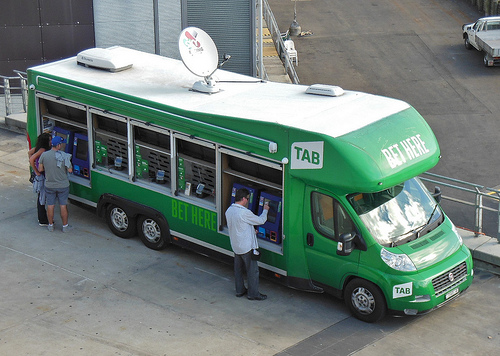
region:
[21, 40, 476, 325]
A big green truck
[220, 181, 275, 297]
A person standing near the truck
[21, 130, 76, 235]
Two people standing together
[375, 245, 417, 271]
The right headlight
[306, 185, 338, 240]
The right side window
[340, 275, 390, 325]
The front tire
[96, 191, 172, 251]
The back tires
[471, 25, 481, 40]
Part of the white truck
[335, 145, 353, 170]
The green part of the truck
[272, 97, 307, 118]
The white part of the truck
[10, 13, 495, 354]
people standing at green bus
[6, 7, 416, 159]
satellite on top of bus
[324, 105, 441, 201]
white righting on front of bus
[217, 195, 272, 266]
man wearing white shirt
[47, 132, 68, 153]
person wearing blue hat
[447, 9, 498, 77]
white truck parked in background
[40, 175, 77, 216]
person wearing blue jean shorts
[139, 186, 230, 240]
green writing on bus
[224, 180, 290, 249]
blue machine on bus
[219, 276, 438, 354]
grey line on ground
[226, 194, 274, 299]
a person wearing a blue shirt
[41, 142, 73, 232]
a man wearing a green shirt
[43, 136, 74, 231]
a man wearing a blue cap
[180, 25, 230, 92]
a satellite on top of the bus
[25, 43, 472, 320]
a green bus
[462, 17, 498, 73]
a white truck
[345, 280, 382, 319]
the tire of the bus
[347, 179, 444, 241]
the windshield of the bus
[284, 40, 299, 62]
white chairs on the street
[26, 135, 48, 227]
a woman with brown hair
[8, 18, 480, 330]
a green and white truck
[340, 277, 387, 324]
the front wheel of a truck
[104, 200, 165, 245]
the rear wheels of a truck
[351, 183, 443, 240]
the windshield of a truck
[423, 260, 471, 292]
the grill of a truck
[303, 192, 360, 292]
the side door of a truck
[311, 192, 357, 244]
the passenger window of a truck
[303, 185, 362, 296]
the passenger door of a truck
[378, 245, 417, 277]
the headlight of a truck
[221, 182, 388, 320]
a man standing beside a truck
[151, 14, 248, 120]
a sattelite on the roof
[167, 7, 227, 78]
a sattelite on the roof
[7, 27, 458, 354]
the truck is green